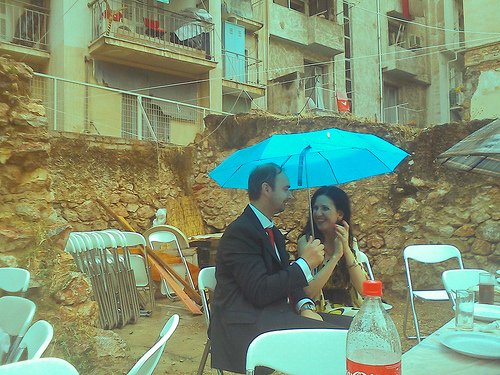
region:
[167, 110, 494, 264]
the umbrella is blue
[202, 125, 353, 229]
the umbrella is blue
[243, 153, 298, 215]
the head of a man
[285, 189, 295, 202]
the nose of a man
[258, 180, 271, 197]
the ear of a man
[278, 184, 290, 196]
the eye of a man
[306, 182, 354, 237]
the head of a woman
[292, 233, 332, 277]
the hand of a man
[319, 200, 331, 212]
the eye of a woman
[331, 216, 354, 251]
the hand of a woman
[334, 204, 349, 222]
the ear of a woman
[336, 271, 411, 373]
a plastic bottle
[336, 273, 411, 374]
A plastic bottle is in the foreground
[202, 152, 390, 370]
A man and a woman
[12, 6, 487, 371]
Photo was taken outside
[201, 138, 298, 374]
Man is wearing a suit and tie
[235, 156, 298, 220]
Man has dark short hair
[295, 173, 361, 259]
Woman has long dark hair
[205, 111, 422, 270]
Man is holding an umbralla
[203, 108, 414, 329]
Umbralla is light blue in color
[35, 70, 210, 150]
A white fence is in the background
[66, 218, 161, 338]
Folded chairs are in the background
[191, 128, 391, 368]
A couple looking at eachother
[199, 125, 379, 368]
Man holding a blue umbrella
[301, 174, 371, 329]
Woman smiling at a man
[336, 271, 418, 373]
Top of a coke bottle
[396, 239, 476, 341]
Empty white folding chair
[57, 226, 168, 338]
Stack of folded white chairs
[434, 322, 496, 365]
White plate on a table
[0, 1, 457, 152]
Apartment buildings with porches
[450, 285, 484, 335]
Empty glass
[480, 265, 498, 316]
Almost full glass of brown liquid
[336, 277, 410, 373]
a coke bottle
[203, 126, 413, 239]
a couple under an umbrella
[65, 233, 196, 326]
row of metal chairs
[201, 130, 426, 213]
a blue umbrella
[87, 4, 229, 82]
a building balconey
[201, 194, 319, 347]
a man in business suit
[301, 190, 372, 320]
a woman smiling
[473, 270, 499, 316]
a glass of soda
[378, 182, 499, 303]
a wall of rocks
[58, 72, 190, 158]
a white chain fence